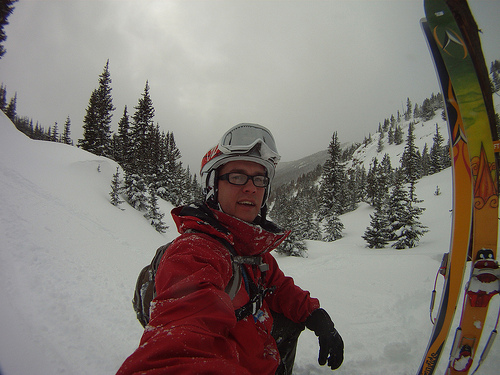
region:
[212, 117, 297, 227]
a man wearing glasses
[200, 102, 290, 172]
a man wearing goggles on his head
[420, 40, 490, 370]
a pair of snow skis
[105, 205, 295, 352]
a man wearing a red coat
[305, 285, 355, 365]
a man wearing black gloves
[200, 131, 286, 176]
a man wearing a helmet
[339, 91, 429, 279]
a hillside covered with snow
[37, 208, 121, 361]
tracks in the snow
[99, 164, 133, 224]
a small tree covered with snow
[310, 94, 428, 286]
several trees covered with snow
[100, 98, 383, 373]
man skiing on mountain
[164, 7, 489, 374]
man holding pair of skis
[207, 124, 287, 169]
white ski goggles on helmet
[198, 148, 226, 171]
white and red helmet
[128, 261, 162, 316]
brown backpack on person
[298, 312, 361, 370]
black snow gloves on hand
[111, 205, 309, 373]
large red snow jacket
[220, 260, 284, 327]
grey and black straps on chest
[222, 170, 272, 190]
black glasses on face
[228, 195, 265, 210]
open mouth of man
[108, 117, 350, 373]
Man taking a selfie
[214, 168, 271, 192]
Pair of clear spectacles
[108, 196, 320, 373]
Thick red jacket with speckles of snow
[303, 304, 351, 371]
Hand in a dark glove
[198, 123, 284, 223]
Head in a helmet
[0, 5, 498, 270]
Valley covered with trees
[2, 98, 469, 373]
Snow covered vast area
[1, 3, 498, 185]
Very thick misty sky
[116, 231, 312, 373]
Straps on the front of jacket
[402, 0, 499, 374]
Pair of multi-colore skis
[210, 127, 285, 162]
Goggles on man's head.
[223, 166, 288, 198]
Glasses on man's face.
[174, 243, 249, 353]
Man wearing red coat.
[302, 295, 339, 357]
Man wearing black glove.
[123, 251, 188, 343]
Back pack on man's back.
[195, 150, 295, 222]
Man wearing helmet on head.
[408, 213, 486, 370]
Yellow skis near man.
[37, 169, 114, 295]
Ground is covered in snow.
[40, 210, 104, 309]
Snow on ground is white.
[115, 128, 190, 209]
Many trees on mountainside.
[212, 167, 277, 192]
a man wearing glasses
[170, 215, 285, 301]
a man wearing a red coat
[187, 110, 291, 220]
a man wearing a helmet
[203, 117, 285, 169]
a man with goggles on his head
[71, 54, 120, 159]
a pine tree covered with snow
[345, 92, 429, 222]
a mountain side covered with snow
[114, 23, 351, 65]
dark clouds in the sky